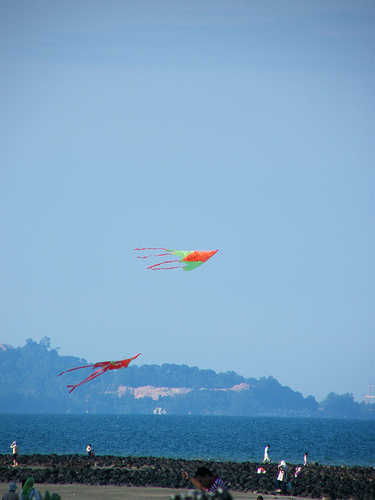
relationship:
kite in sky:
[53, 351, 145, 390] [33, 102, 339, 406]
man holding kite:
[176, 462, 230, 498] [53, 351, 145, 390]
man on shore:
[7, 438, 20, 466] [7, 460, 62, 470]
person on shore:
[261, 442, 273, 465] [244, 456, 288, 468]